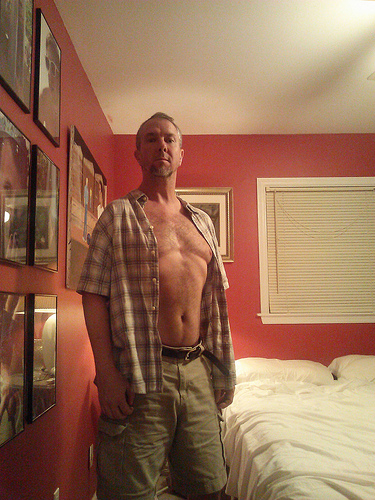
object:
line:
[181, 436, 216, 451]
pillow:
[325, 354, 374, 383]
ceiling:
[49, 0, 374, 138]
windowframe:
[255, 175, 375, 325]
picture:
[34, 8, 60, 147]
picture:
[30, 145, 60, 277]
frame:
[64, 125, 108, 287]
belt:
[160, 347, 227, 376]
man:
[76, 111, 238, 499]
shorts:
[95, 343, 228, 499]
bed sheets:
[221, 380, 374, 500]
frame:
[175, 187, 234, 265]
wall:
[114, 133, 374, 380]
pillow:
[234, 356, 333, 386]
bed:
[217, 353, 375, 500]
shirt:
[73, 189, 236, 390]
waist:
[113, 338, 207, 360]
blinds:
[264, 184, 374, 316]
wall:
[1, 1, 115, 499]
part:
[218, 378, 374, 498]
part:
[235, 355, 334, 387]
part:
[204, 430, 223, 449]